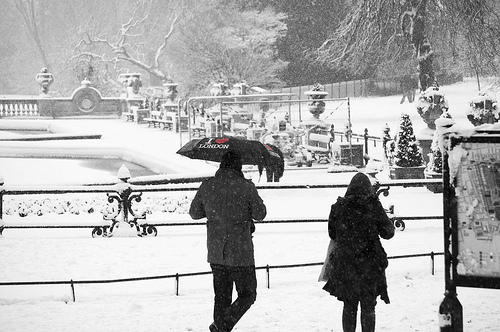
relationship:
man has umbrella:
[188, 152, 270, 331] [175, 134, 286, 181]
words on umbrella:
[197, 134, 230, 153] [175, 134, 286, 181]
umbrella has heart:
[175, 134, 286, 181] [213, 136, 230, 148]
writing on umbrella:
[197, 134, 230, 153] [175, 134, 286, 181]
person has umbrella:
[188, 152, 270, 331] [175, 134, 286, 181]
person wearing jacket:
[326, 174, 392, 331] [326, 195, 392, 292]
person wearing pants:
[326, 174, 392, 331] [329, 261, 374, 332]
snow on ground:
[1, 4, 489, 327] [14, 104, 499, 331]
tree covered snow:
[319, 1, 482, 87] [1, 4, 489, 327]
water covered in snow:
[3, 150, 163, 187] [10, 157, 129, 189]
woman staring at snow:
[326, 174, 392, 331] [1, 4, 489, 327]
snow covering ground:
[1, 4, 489, 327] [14, 104, 499, 331]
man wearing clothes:
[188, 152, 270, 331] [202, 174, 260, 275]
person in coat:
[326, 174, 392, 331] [326, 195, 392, 292]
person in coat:
[188, 152, 270, 331] [192, 168, 270, 268]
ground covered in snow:
[14, 104, 499, 331] [1, 4, 489, 327]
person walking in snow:
[326, 174, 392, 331] [1, 4, 489, 327]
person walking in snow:
[188, 152, 270, 331] [1, 4, 489, 327]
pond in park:
[3, 150, 163, 187] [2, 79, 495, 322]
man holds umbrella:
[188, 152, 270, 331] [175, 134, 286, 181]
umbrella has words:
[175, 134, 286, 181] [197, 134, 230, 153]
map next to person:
[438, 130, 499, 287] [326, 174, 392, 331]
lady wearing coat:
[326, 174, 392, 331] [326, 195, 392, 292]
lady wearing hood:
[326, 174, 392, 331] [345, 173, 376, 203]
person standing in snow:
[326, 174, 392, 331] [1, 4, 489, 327]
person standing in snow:
[188, 152, 270, 331] [1, 4, 489, 327]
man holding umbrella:
[188, 152, 270, 331] [175, 134, 286, 181]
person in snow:
[326, 174, 392, 331] [1, 4, 489, 327]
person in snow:
[188, 152, 270, 331] [1, 4, 489, 327]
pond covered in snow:
[3, 150, 163, 187] [10, 157, 129, 189]